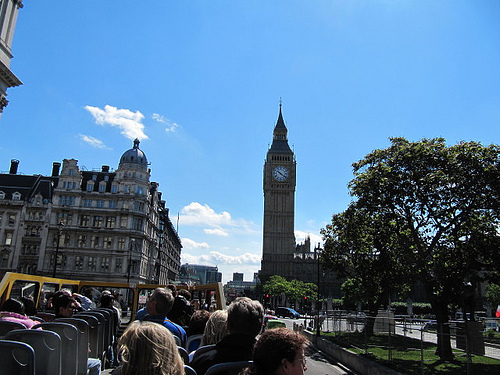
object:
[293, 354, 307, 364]
glasses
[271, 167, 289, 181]
clock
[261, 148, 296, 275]
pillar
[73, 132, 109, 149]
cloud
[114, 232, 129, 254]
window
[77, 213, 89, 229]
window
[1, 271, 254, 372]
tour bus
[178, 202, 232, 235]
white cloud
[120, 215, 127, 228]
window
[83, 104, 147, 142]
clouds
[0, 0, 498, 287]
sky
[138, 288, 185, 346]
man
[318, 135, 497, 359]
tree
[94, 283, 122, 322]
person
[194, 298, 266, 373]
person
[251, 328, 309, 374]
person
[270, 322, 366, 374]
street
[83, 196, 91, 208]
window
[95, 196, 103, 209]
window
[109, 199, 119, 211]
window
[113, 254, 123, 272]
window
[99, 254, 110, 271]
window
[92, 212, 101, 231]
window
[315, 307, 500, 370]
fence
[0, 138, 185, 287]
top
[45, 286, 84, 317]
tourist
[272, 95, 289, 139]
top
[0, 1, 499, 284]
view